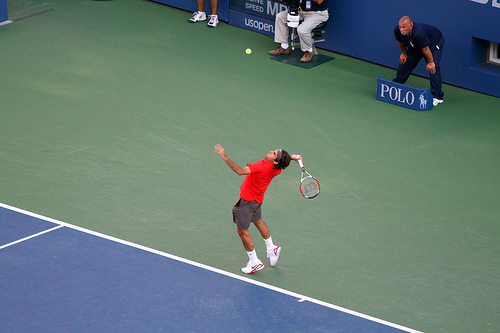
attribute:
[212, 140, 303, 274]
tennis player — male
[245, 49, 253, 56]
tennis ball — green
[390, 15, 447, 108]
man — bald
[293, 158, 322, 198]
tennis racket — red, white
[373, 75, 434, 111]
sign — small, blue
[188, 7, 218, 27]
tennis shoes — white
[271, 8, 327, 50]
pants — khaki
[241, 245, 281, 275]
tennis shoes — white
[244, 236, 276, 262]
socks — white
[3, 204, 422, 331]
lines — white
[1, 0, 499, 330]
surface — green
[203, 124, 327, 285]
player — tennis 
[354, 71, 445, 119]
sign — small polo Ralph Lauren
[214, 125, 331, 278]
player — tennis n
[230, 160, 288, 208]
t-shirt — red 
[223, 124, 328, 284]
player — tennis 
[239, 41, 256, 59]
ball — tennis 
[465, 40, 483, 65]
window — small 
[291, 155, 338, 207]
racket — Wilson tennis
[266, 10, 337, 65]
judge — tennis court 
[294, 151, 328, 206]
racket —  blue tennisd , red white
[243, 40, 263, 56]
ball — yellow tennis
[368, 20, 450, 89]
official — blue, tennis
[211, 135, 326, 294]
man — gray head band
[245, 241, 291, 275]
shoes — white tennis , red , black detail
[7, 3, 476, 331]
court — blue tennis, green tennis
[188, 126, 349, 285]
player — tennis 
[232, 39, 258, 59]
ball — tennis 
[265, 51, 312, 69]
loafers — mens brown dress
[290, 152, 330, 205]
racket — white tennis , red  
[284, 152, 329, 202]
racket — white tennis, red 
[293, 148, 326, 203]
racket — white tennis, red 